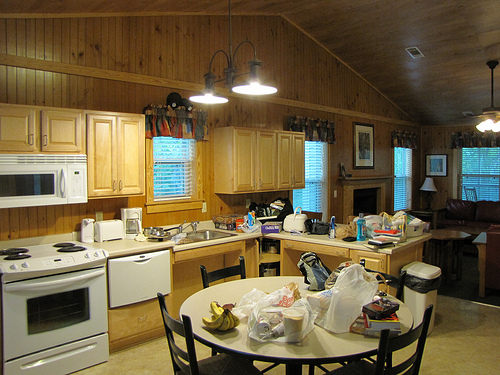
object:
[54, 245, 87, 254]
stove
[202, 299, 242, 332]
bunch of bananas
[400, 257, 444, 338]
garbage can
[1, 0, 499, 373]
kitchen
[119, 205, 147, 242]
coffee maker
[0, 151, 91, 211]
microwave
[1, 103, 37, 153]
cabinet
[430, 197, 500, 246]
sofa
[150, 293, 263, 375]
chair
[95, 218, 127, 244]
toaster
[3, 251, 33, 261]
burners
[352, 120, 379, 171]
picture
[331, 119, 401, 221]
wall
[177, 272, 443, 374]
kitchen table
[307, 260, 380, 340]
grocery bags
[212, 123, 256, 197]
cupboards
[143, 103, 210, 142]
valance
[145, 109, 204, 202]
window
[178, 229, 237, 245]
sink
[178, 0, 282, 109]
light fixtures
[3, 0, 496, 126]
ceiling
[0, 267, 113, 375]
oven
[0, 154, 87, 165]
microwave range hood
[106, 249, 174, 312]
dishwasher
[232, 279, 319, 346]
plastic bag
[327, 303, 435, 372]
chair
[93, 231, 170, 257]
counter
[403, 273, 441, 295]
bag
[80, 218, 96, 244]
can opener